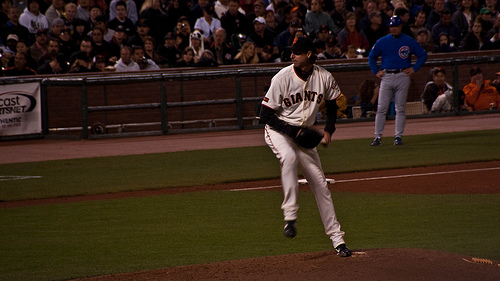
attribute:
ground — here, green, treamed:
[1, 128, 499, 280]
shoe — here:
[336, 243, 355, 258]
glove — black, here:
[294, 128, 323, 151]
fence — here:
[1, 56, 500, 144]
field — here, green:
[2, 114, 500, 279]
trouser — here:
[374, 69, 411, 140]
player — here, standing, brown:
[258, 35, 353, 257]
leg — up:
[263, 125, 299, 237]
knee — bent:
[277, 148, 300, 168]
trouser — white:
[264, 124, 347, 250]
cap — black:
[286, 36, 315, 55]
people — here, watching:
[1, 0, 500, 78]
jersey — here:
[263, 65, 345, 131]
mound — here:
[69, 246, 498, 280]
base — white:
[295, 176, 337, 186]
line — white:
[232, 166, 499, 192]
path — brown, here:
[2, 162, 500, 209]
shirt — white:
[260, 62, 341, 129]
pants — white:
[265, 124, 348, 250]